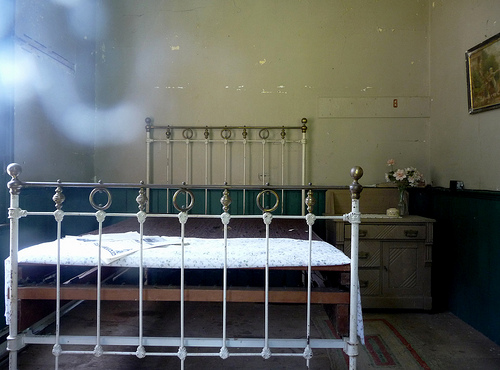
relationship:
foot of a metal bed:
[6, 166, 365, 370] [6, 119, 361, 369]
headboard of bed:
[142, 116, 309, 184] [6, 119, 361, 369]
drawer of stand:
[343, 223, 430, 240] [326, 184, 437, 311]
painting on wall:
[465, 31, 499, 114] [426, 3, 498, 344]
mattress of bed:
[12, 234, 349, 265] [6, 119, 361, 369]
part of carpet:
[429, 313, 498, 370] [0, 300, 498, 369]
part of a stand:
[308, 288, 348, 303] [16, 282, 349, 335]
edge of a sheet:
[355, 276, 366, 346] [0, 229, 365, 348]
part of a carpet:
[429, 313, 498, 370] [0, 300, 498, 369]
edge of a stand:
[355, 276, 366, 346] [16, 282, 349, 335]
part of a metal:
[315, 212, 342, 224] [17, 207, 353, 222]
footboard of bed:
[4, 163, 368, 369] [6, 119, 361, 369]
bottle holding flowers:
[399, 182, 411, 215] [382, 166, 425, 187]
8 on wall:
[389, 96, 401, 112] [1, 3, 431, 303]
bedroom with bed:
[0, 1, 498, 369] [6, 119, 361, 369]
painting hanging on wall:
[465, 31, 499, 114] [426, 3, 498, 344]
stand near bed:
[326, 184, 437, 311] [6, 119, 361, 369]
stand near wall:
[326, 184, 437, 311] [426, 3, 498, 344]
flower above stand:
[369, 159, 429, 218] [326, 184, 437, 311]